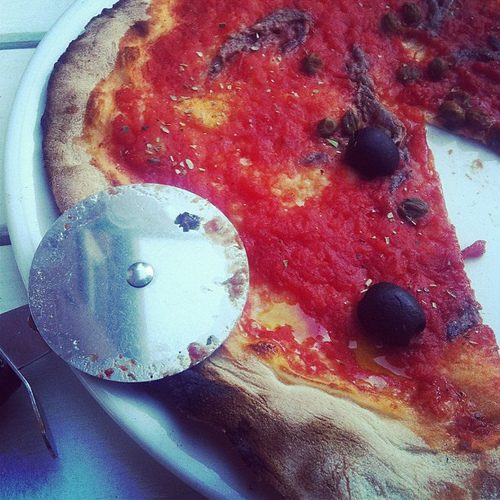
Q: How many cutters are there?
A: One.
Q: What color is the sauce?
A: Red.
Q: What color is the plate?
A: White.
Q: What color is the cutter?
A: Silver.